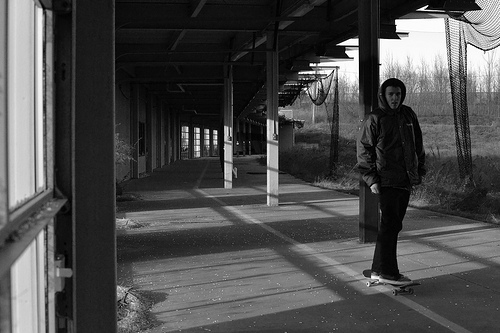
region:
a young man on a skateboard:
[356, 74, 423, 289]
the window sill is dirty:
[1, 194, 68, 259]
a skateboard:
[361, 266, 419, 296]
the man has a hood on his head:
[373, 76, 407, 111]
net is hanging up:
[440, 4, 499, 187]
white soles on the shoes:
[369, 275, 411, 285]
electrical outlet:
[271, 35, 277, 140]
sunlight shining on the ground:
[143, 222, 492, 329]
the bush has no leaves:
[113, 124, 139, 168]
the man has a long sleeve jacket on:
[353, 75, 428, 196]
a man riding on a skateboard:
[347, 67, 424, 301]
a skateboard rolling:
[360, 260, 420, 300]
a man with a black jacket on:
[353, 74, 448, 212]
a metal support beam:
[252, 19, 292, 223]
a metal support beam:
[211, 51, 245, 203]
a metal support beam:
[352, 10, 405, 260]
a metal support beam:
[67, 5, 135, 329]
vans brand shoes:
[362, 260, 417, 288]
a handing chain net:
[438, 6, 498, 188]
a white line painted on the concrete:
[183, 136, 436, 327]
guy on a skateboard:
[337, 65, 430, 282]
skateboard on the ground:
[354, 253, 411, 302]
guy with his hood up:
[376, 70, 404, 110]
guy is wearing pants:
[360, 162, 430, 299]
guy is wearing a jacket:
[343, 64, 428, 209]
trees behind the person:
[380, 36, 474, 156]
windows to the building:
[165, 114, 217, 181]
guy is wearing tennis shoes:
[360, 245, 407, 314]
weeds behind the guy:
[421, 136, 485, 218]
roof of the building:
[126, 10, 333, 167]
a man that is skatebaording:
[277, 66, 493, 273]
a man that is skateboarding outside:
[282, 51, 466, 306]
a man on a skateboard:
[340, 74, 474, 283]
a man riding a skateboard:
[355, 56, 395, 238]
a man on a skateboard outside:
[348, 56, 450, 327]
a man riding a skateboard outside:
[347, 65, 450, 325]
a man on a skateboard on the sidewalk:
[297, 74, 474, 321]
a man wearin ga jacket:
[364, 66, 474, 331]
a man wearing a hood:
[314, 49, 471, 284]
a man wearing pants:
[339, 65, 416, 292]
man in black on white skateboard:
[351, 69, 434, 291]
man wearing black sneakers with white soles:
[362, 272, 414, 284]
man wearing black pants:
[369, 179, 412, 276]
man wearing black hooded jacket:
[352, 75, 424, 187]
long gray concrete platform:
[125, 134, 499, 329]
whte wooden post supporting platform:
[265, 2, 282, 209]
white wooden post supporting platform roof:
[220, 39, 243, 190]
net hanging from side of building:
[443, 0, 497, 190]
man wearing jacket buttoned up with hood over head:
[352, 75, 429, 185]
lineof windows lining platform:
[177, 120, 224, 160]